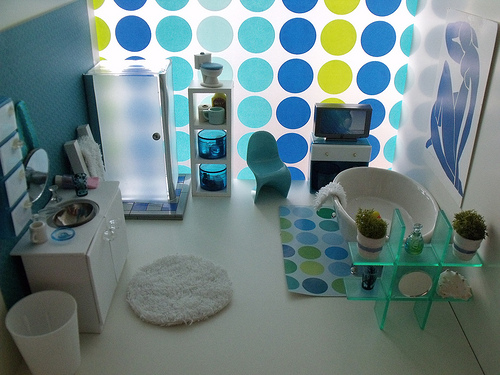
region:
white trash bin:
[5, 293, 83, 371]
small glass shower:
[85, 60, 179, 202]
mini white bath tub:
[333, 168, 438, 242]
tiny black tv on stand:
[312, 105, 369, 142]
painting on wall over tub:
[402, 5, 499, 207]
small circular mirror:
[25, 150, 50, 198]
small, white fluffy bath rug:
[125, 255, 233, 326]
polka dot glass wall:
[88, 0, 416, 183]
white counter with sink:
[13, 180, 133, 330]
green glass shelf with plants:
[347, 205, 481, 332]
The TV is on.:
[300, 92, 386, 152]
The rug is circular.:
[122, 245, 249, 341]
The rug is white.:
[122, 244, 240, 337]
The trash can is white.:
[4, 284, 89, 363]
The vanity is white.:
[21, 175, 151, 335]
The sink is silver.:
[47, 192, 99, 228]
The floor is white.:
[113, 176, 413, 373]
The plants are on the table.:
[344, 198, 497, 291]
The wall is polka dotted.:
[93, 6, 415, 208]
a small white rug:
[107, 233, 244, 350]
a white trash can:
[0, 280, 116, 372]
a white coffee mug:
[14, 213, 57, 263]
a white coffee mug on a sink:
[16, 203, 56, 247]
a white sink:
[6, 145, 194, 369]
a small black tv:
[293, 81, 398, 156]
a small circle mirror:
[6, 129, 72, 233]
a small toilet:
[178, 47, 245, 104]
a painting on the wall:
[419, 3, 499, 241]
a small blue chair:
[230, 113, 320, 233]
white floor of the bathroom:
[279, 315, 352, 370]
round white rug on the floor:
[137, 245, 231, 337]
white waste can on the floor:
[4, 282, 91, 374]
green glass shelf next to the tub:
[350, 213, 487, 344]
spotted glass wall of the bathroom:
[238, 5, 312, 113]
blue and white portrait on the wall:
[424, 25, 496, 197]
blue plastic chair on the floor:
[241, 128, 297, 211]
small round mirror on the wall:
[30, 143, 49, 208]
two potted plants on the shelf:
[346, 203, 495, 268]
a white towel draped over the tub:
[306, 175, 350, 213]